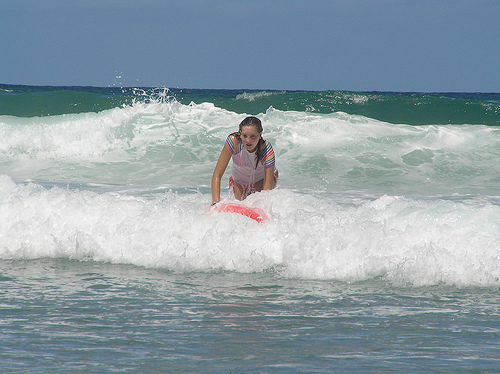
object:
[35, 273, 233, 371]
calmer/rippled water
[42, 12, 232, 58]
dark-blue-sky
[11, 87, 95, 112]
greenest section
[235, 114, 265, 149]
head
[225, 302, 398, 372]
small ripples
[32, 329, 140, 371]
small ripples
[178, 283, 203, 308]
ripples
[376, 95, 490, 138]
water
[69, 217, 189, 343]
ripples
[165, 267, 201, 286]
ripples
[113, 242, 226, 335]
ripples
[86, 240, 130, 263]
ripples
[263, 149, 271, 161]
stripes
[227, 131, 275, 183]
shirt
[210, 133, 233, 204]
arm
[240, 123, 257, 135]
forehead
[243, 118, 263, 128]
hair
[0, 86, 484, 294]
wave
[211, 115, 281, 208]
female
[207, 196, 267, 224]
board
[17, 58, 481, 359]
ocean